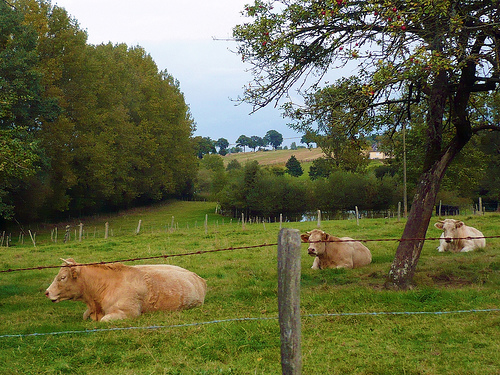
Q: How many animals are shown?
A: Three.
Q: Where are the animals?
A: Field.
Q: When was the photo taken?
A: Daytime.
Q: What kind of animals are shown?
A: Cows.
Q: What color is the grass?
A: Green.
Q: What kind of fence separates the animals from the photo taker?
A: Barb wire fence.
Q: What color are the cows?
A: Brown.